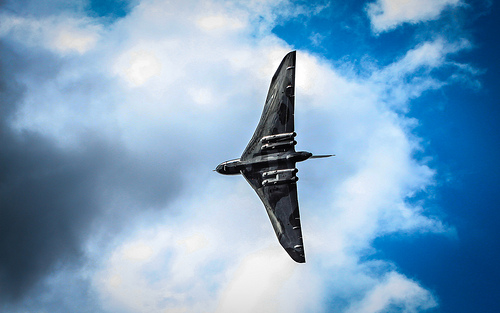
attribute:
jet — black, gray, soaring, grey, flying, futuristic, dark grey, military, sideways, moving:
[212, 50, 335, 263]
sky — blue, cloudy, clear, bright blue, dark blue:
[0, 2, 499, 312]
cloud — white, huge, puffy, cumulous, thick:
[12, 1, 441, 312]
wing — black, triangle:
[240, 50, 301, 160]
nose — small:
[213, 157, 244, 175]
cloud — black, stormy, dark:
[0, 25, 183, 313]